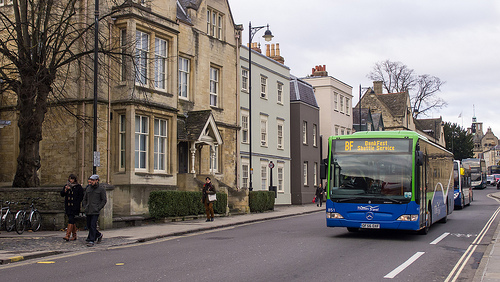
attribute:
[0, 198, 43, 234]
bicycles — black, parked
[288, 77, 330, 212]
building — dark brown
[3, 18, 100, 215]
tree — large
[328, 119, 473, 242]
bus — blue, green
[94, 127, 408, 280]
street — black, paved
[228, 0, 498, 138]
sky — grey, cloudy, overcast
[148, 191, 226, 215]
bushes — trimmed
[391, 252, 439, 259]
line — white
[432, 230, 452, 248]
line — white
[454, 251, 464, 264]
line — white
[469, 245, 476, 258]
line — white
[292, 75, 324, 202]
building — dark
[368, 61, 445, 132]
tree — tall, bare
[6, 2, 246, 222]
residence — yellow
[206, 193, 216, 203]
bag — white